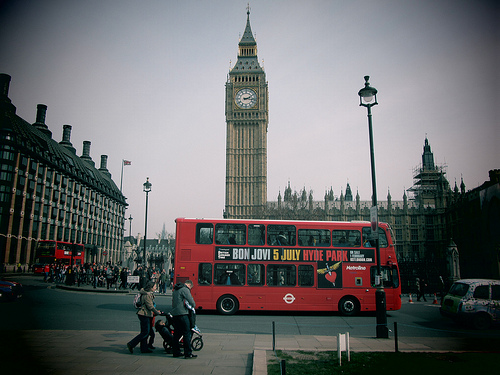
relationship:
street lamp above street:
[357, 74, 389, 339] [9, 270, 497, 341]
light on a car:
[456, 300, 463, 312] [436, 274, 499, 330]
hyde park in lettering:
[302, 247, 348, 260] [303, 247, 350, 259]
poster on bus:
[210, 246, 373, 267] [171, 211, 404, 318]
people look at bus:
[111, 272, 212, 360] [171, 211, 404, 318]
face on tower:
[234, 88, 259, 112] [225, 4, 267, 219]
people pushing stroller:
[117, 276, 203, 356] [154, 310, 204, 353]